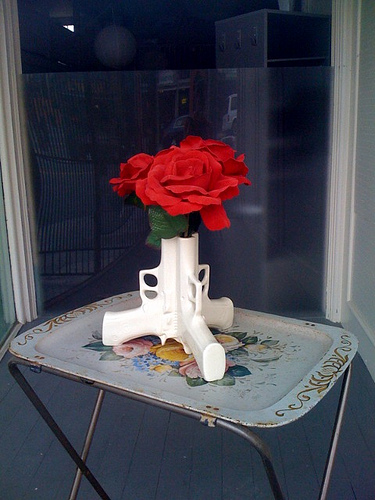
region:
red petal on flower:
[203, 207, 231, 233]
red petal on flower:
[184, 191, 221, 209]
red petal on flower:
[163, 201, 199, 215]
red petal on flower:
[143, 186, 180, 207]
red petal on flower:
[134, 178, 151, 205]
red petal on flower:
[233, 173, 251, 186]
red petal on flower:
[161, 173, 196, 186]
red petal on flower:
[224, 153, 248, 176]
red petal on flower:
[127, 153, 152, 165]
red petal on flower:
[118, 163, 141, 176]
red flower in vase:
[105, 136, 264, 246]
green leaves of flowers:
[121, 158, 221, 238]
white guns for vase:
[107, 226, 244, 408]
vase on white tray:
[66, 270, 324, 483]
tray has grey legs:
[11, 286, 332, 494]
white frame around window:
[303, 15, 372, 281]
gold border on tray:
[279, 337, 356, 438]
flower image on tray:
[116, 318, 251, 367]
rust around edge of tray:
[61, 348, 348, 434]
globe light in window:
[72, 1, 148, 90]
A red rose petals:
[118, 130, 281, 234]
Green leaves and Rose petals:
[110, 128, 248, 251]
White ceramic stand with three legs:
[98, 135, 257, 386]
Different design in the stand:
[102, 231, 261, 381]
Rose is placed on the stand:
[95, 150, 249, 376]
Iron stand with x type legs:
[17, 292, 360, 440]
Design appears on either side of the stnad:
[2, 270, 372, 496]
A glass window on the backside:
[22, 44, 338, 316]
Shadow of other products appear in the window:
[9, 6, 369, 398]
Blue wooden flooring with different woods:
[2, 2, 372, 498]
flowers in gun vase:
[80, 119, 257, 383]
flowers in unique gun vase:
[84, 126, 272, 389]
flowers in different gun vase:
[71, 128, 274, 386]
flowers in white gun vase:
[77, 126, 272, 401]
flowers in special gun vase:
[75, 125, 269, 386]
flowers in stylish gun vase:
[72, 128, 274, 399]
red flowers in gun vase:
[79, 126, 281, 391]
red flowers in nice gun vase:
[83, 132, 281, 400]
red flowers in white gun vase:
[77, 128, 279, 406]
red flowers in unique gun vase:
[61, 124, 279, 388]